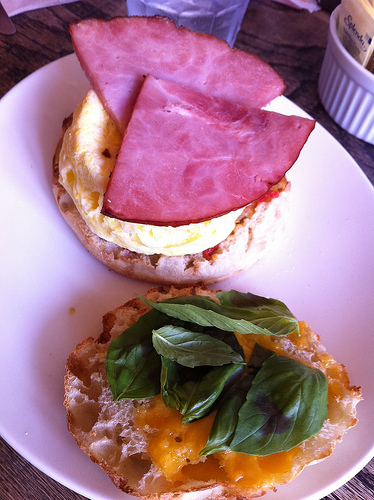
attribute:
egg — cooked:
[54, 89, 245, 254]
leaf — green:
[139, 292, 302, 334]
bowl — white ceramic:
[314, 4, 373, 148]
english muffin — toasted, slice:
[55, 74, 254, 235]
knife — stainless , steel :
[1, 5, 15, 36]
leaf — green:
[203, 373, 236, 470]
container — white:
[313, 0, 372, 137]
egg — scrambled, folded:
[61, 87, 284, 248]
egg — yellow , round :
[61, 88, 116, 232]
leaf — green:
[150, 323, 248, 367]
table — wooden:
[1, 1, 372, 498]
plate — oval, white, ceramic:
[0, 49, 373, 497]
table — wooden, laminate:
[8, 7, 365, 125]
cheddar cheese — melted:
[135, 398, 280, 484]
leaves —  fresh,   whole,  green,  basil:
[114, 303, 328, 422]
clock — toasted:
[251, 190, 312, 269]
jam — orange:
[145, 410, 180, 452]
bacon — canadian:
[78, 14, 322, 217]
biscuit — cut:
[135, 241, 276, 278]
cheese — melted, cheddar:
[148, 355, 312, 483]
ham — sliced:
[72, 18, 316, 213]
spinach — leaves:
[105, 289, 329, 456]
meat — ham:
[108, 63, 278, 228]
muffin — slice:
[52, 74, 292, 289]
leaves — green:
[103, 287, 330, 456]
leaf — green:
[131, 290, 301, 336]